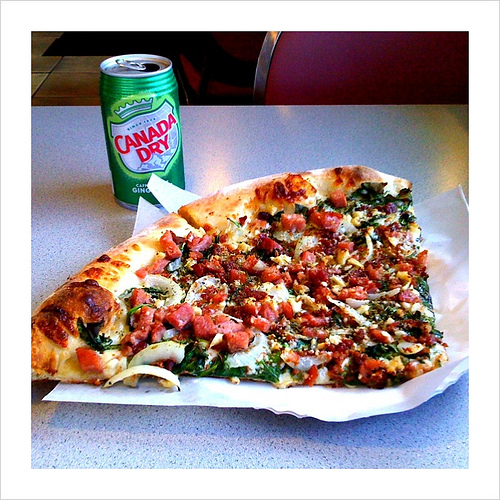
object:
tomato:
[74, 346, 103, 375]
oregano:
[182, 346, 250, 378]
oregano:
[350, 183, 413, 206]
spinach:
[123, 300, 153, 330]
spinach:
[253, 350, 287, 382]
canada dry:
[113, 113, 180, 165]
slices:
[28, 164, 447, 392]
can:
[97, 53, 185, 212]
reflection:
[195, 144, 232, 196]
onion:
[104, 363, 182, 393]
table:
[31, 104, 469, 468]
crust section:
[29, 211, 181, 379]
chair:
[251, 31, 468, 106]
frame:
[250, 32, 282, 105]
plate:
[39, 172, 467, 424]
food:
[31, 166, 446, 391]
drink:
[99, 52, 188, 211]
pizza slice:
[177, 165, 445, 367]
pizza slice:
[28, 208, 398, 392]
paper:
[40, 171, 468, 423]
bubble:
[35, 279, 119, 344]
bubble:
[251, 171, 313, 210]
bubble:
[324, 163, 383, 202]